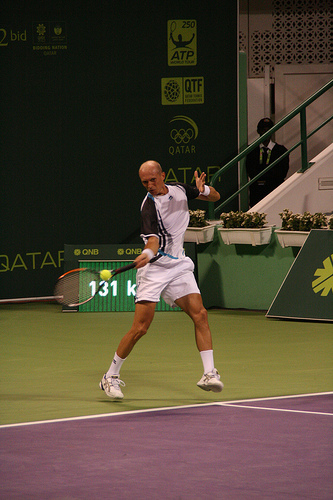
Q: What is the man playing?
A: Tennis.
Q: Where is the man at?
A: Tennis court.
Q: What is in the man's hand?
A: Tennis racket.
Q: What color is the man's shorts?
A: White.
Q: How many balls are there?
A: One.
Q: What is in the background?
A: Plants.